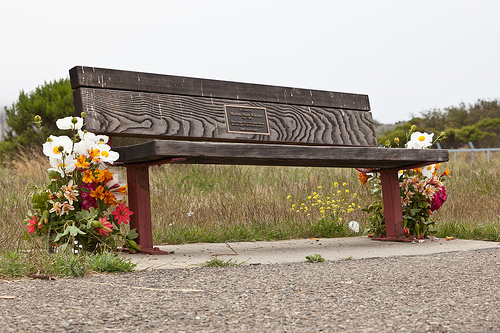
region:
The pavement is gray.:
[231, 270, 343, 321]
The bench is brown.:
[68, 63, 448, 173]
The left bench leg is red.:
[123, 167, 159, 244]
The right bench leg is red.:
[371, 171, 423, 238]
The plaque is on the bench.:
[218, 102, 275, 136]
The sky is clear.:
[365, 34, 448, 69]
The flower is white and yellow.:
[404, 127, 435, 149]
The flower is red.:
[109, 198, 134, 226]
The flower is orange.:
[88, 183, 106, 203]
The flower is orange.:
[81, 168, 97, 187]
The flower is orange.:
[101, 186, 119, 209]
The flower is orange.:
[73, 153, 91, 172]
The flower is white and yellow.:
[41, 133, 72, 160]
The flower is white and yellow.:
[89, 138, 119, 166]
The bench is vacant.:
[59, 61, 452, 273]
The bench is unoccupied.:
[58, 51, 463, 268]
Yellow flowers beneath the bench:
[286, 182, 361, 234]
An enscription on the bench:
[224, 104, 271, 136]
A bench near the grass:
[67, 67, 445, 243]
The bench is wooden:
[68, 66, 447, 256]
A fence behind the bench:
[445, 147, 495, 165]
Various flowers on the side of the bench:
[23, 115, 137, 252]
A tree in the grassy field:
[5, 79, 72, 161]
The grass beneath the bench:
[0, 164, 499, 281]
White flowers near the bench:
[43, 116, 118, 175]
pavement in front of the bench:
[21, 260, 498, 315]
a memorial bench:
[40, 53, 456, 259]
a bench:
[73, 51, 409, 268]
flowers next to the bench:
[31, 118, 122, 232]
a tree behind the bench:
[12, 77, 64, 123]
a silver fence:
[438, 140, 496, 157]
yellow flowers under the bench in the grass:
[294, 180, 367, 222]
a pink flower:
[110, 198, 134, 221]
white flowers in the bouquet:
[42, 110, 97, 165]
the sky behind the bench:
[9, 8, 458, 63]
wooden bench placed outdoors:
[25, 32, 480, 273]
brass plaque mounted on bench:
[215, 96, 277, 136]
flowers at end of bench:
[25, 101, 135, 263]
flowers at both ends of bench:
[15, 97, 456, 253]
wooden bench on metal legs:
[65, 63, 474, 249]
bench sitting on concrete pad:
[50, 57, 497, 247]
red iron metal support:
[368, 165, 418, 246]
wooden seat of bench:
[111, 142, 451, 175]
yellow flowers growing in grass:
[281, 170, 363, 232]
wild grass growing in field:
[181, 169, 310, 236]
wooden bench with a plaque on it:
[65, 61, 452, 251]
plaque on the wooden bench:
[223, 99, 271, 137]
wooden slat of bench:
[73, 85, 378, 147]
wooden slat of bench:
[90, 134, 186, 161]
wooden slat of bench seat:
[108, 139, 449, 167]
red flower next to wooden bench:
[111, 198, 133, 224]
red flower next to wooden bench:
[25, 212, 39, 236]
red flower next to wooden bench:
[95, 214, 113, 236]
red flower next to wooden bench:
[78, 180, 97, 209]